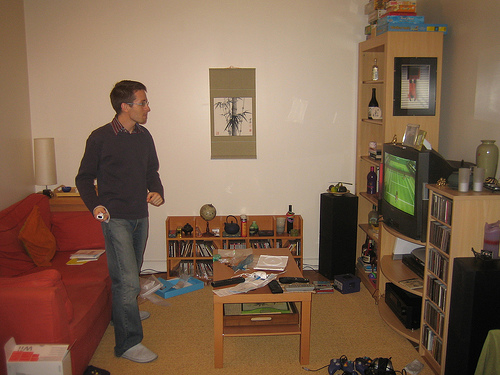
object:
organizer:
[161, 213, 305, 288]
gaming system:
[327, 271, 365, 295]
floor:
[89, 269, 435, 373]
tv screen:
[372, 135, 451, 246]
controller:
[90, 204, 113, 227]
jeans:
[94, 210, 159, 355]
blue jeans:
[100, 222, 150, 345]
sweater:
[70, 122, 170, 225]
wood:
[401, 163, 500, 375]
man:
[66, 79, 188, 374]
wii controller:
[88, 199, 114, 229]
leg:
[212, 292, 224, 372]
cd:
[442, 194, 450, 226]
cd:
[437, 224, 448, 252]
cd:
[437, 257, 451, 282]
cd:
[428, 305, 435, 327]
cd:
[424, 325, 432, 355]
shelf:
[425, 207, 455, 232]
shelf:
[424, 235, 451, 260]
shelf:
[421, 293, 449, 320]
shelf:
[417, 317, 449, 347]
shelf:
[357, 113, 387, 131]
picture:
[206, 58, 272, 160]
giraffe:
[367, 145, 422, 219]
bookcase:
[338, 25, 444, 301]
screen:
[380, 150, 422, 222]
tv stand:
[371, 215, 431, 343]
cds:
[430, 192, 452, 227]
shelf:
[428, 213, 453, 230]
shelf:
[328, 20, 465, 313]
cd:
[429, 226, 447, 240]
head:
[103, 65, 167, 148]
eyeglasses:
[111, 90, 158, 109]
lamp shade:
[28, 125, 63, 197]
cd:
[427, 277, 445, 311]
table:
[205, 245, 315, 364]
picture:
[208, 65, 259, 161]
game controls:
[312, 350, 405, 374]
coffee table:
[207, 246, 317, 368]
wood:
[211, 247, 320, 369]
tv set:
[370, 138, 459, 237]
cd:
[426, 217, 452, 247]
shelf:
[414, 180, 466, 355]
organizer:
[419, 177, 496, 374]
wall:
[24, 0, 367, 271]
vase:
[474, 134, 498, 190]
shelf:
[425, 179, 498, 199]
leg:
[297, 294, 312, 368]